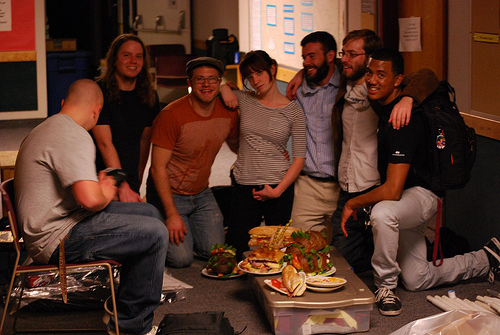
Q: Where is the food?
A: In the middle of the people.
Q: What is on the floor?
A: Carpet.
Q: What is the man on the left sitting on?
A: A chair.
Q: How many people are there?
A: Seven.